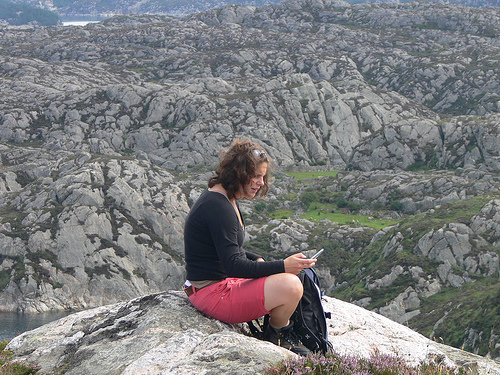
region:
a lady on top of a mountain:
[172, 145, 349, 356]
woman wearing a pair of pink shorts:
[193, 280, 277, 327]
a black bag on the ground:
[296, 262, 327, 357]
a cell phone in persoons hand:
[308, 243, 320, 262]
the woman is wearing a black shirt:
[181, 177, 258, 298]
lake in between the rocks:
[7, 300, 59, 350]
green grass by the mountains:
[293, 173, 380, 247]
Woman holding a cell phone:
[183, 138, 323, 355]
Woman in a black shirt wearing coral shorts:
[183, 138, 307, 324]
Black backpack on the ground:
[283, 265, 330, 355]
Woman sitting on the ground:
[183, 140, 316, 359]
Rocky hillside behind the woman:
[3, 2, 499, 362]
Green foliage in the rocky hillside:
[275, 150, 497, 358]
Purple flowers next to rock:
[269, 348, 483, 373]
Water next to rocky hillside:
[0, 301, 107, 347]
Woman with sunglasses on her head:
[205, 138, 277, 227]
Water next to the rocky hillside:
[52, 6, 136, 28]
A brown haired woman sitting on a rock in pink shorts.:
[183, 141, 316, 356]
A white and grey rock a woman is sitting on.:
[0, 286, 498, 373]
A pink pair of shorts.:
[182, 274, 268, 326]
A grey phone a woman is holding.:
[310, 248, 323, 262]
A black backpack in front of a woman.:
[290, 266, 336, 356]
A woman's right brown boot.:
[266, 322, 313, 357]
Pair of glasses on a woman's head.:
[251, 146, 266, 158]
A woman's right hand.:
[283, 252, 316, 273]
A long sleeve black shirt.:
[185, 185, 285, 280]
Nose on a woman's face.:
[255, 175, 265, 187]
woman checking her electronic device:
[180, 137, 325, 353]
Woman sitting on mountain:
[180, 136, 325, 356]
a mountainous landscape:
[0, 6, 496, 281]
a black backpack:
[260, 265, 331, 355]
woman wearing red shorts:
[182, 135, 322, 355]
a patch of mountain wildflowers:
[257, 342, 477, 369]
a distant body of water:
[56, 15, 96, 25]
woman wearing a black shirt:
[180, 137, 315, 354]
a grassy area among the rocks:
[265, 165, 410, 222]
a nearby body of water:
[0, 308, 67, 342]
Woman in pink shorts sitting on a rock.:
[184, 142, 311, 356]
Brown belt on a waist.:
[182, 279, 222, 295]